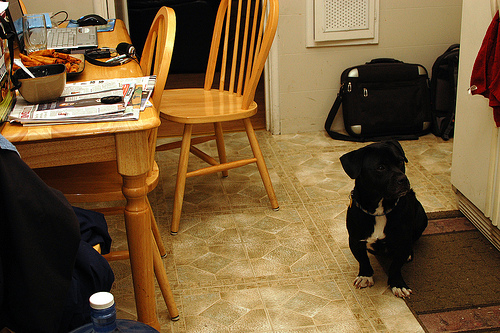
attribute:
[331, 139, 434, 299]
dog — black, sitting, white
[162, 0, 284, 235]
chair — wooden, brown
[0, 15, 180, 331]
table — wooden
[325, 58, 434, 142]
bag — black, silver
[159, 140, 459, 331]
floor — linoleum, brown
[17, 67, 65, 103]
bowl — brown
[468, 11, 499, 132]
clothing — red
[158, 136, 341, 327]
tiles — brown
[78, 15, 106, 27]
mouse — electronic, black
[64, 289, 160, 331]
jug — blue, clear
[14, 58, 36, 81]
spoon — silver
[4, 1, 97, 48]
laptop — gray, silver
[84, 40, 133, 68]
headphones — black, gray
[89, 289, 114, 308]
lid — white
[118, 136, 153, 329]
leg — wooden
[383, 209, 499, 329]
carpet — brown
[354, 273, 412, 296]
paws — white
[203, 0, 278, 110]
back — wooden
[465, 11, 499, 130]
towel — red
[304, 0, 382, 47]
vent — white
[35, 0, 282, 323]
chairs — wooden